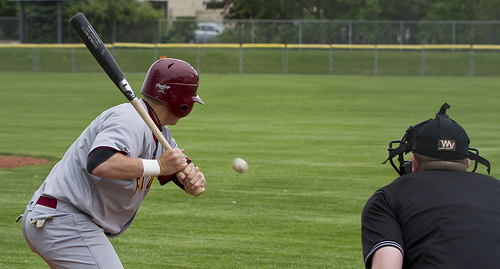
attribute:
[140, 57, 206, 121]
helmet — red, maroon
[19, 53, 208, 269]
batter — up to bat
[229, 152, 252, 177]
ball — flying, white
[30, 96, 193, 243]
shirt — grey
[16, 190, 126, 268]
pants — grey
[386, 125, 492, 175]
mask — black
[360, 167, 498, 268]
shirt — black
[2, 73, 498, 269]
field — big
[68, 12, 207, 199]
bat — black, wooden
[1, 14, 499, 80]
fence — long, chain link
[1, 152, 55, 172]
mound — brown, pitcher's, small, sand, dirt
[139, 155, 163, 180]
sweat band — white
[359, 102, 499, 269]
umpire — watching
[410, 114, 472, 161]
hat — black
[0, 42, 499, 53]
top — yellow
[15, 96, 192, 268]
uniform — grey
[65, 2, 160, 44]
tree — beautiful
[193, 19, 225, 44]
car — parked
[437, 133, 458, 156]
wv — yellow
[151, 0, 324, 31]
building — brown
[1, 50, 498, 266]
grass — mown, green